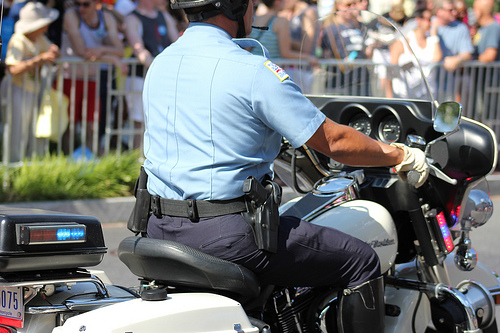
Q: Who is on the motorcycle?
A: The policeman.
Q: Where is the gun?
A: In the holster.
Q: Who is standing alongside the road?
A: Spectators.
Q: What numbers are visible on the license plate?
A: 075.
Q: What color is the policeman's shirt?
A: Blue.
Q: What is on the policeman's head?
A: A helmet.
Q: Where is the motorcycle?
A: In the road.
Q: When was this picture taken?
A: Daytime.